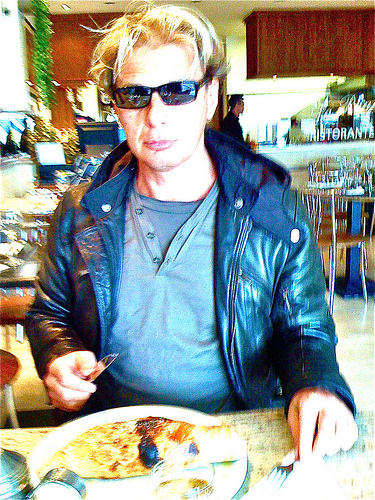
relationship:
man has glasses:
[25, 6, 360, 457] [104, 74, 213, 110]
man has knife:
[25, 6, 360, 457] [89, 351, 118, 386]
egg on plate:
[49, 416, 207, 480] [21, 403, 249, 499]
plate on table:
[21, 403, 249, 499] [2, 408, 373, 498]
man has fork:
[25, 6, 360, 457] [262, 456, 304, 498]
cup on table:
[152, 455, 217, 499] [2, 408, 373, 498]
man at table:
[25, 6, 360, 457] [2, 408, 373, 498]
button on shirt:
[132, 207, 148, 219] [103, 168, 243, 414]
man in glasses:
[25, 6, 360, 457] [104, 74, 213, 110]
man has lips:
[25, 6, 360, 457] [143, 139, 177, 149]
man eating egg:
[25, 6, 360, 457] [49, 416, 207, 480]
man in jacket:
[25, 6, 360, 457] [27, 140, 360, 418]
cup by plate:
[152, 455, 217, 499] [21, 403, 249, 499]